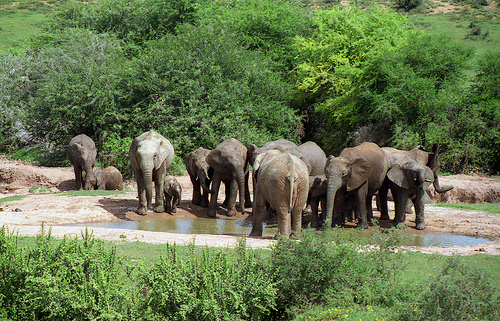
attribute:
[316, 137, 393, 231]
elephant — small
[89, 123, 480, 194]
elephants — standing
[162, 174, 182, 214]
baby elephant — standing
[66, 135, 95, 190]
elephant — dark grey, dry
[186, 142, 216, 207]
elephant — dry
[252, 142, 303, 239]
elephant — dry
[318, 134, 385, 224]
elephant — dry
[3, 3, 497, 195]
trees — green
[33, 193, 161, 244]
dirt — brown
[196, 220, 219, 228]
water — muddy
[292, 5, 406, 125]
tree — lighter green, darker trees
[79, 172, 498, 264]
pool — grey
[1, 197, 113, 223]
dirt — brown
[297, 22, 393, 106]
leaves — light green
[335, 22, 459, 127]
tree — tall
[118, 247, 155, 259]
grass — green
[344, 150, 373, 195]
ear — gray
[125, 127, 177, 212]
elephant — dark grey, dry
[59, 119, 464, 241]
elephants — standing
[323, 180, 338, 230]
trunk — elephant's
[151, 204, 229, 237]
water — between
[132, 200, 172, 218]
elephant feet — wet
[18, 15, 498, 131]
grass background — green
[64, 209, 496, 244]
water — shallow, grey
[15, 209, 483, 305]
forefront — green